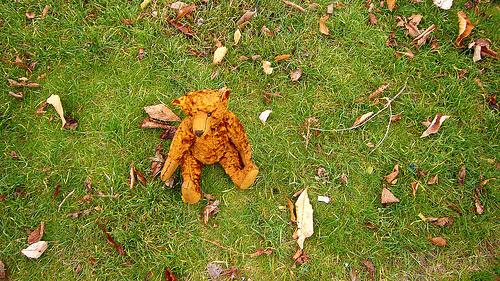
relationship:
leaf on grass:
[46, 85, 75, 121] [8, 15, 480, 267]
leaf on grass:
[209, 40, 232, 70] [8, 15, 480, 267]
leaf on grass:
[230, 9, 255, 31] [8, 15, 480, 267]